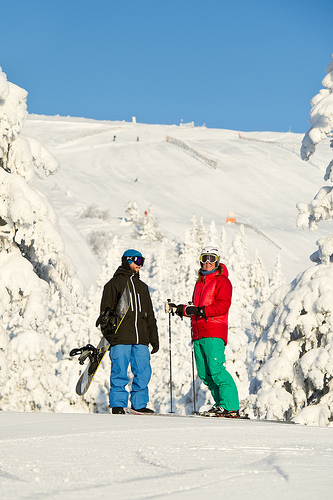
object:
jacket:
[178, 263, 233, 346]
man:
[100, 249, 159, 415]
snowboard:
[75, 275, 137, 396]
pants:
[108, 344, 152, 410]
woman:
[164, 247, 239, 418]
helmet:
[199, 246, 221, 271]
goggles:
[199, 253, 220, 264]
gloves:
[185, 301, 208, 320]